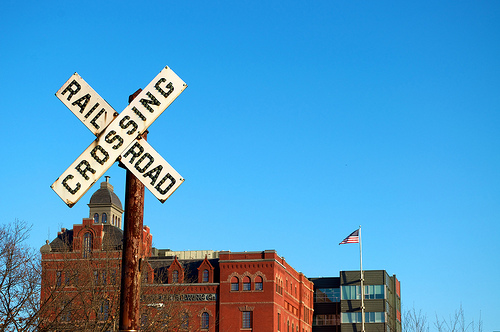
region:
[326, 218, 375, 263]
a flag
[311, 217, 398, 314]
a flag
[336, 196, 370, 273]
a flag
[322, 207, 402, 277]
a flag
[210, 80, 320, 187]
the sky is crystal clear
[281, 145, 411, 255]
the sky is crystal clear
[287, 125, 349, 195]
the sky is crystal clear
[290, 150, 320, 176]
the sky is crystal clear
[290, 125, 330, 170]
the sky is crystal clear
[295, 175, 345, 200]
the sky is crystal clear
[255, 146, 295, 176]
the sky is crystal clear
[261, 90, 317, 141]
the sky is crystal clear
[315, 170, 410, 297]
a flag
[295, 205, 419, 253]
The US flag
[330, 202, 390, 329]
The US flag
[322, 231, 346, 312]
The US flag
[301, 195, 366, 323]
The US flag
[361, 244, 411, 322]
The US flag